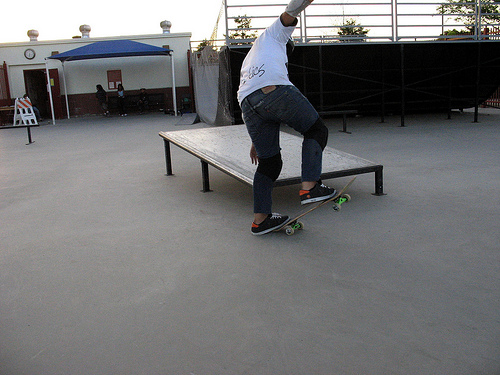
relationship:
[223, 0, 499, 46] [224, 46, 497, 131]
fence on top of wall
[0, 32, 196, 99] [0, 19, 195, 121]
wall of building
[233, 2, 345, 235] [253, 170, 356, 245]
man on skateboard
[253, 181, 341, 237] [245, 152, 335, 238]
sneakers on feet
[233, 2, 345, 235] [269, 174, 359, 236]
man on skateboard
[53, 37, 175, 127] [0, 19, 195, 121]
blue tent set up in front of building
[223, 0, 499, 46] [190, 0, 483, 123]
fence on bleachers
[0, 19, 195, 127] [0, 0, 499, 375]
building in park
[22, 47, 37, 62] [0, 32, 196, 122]
clock on wall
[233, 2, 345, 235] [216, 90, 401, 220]
man wearing jeans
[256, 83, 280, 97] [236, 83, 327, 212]
leather patch on blue jeans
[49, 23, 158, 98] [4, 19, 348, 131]
tent on front of building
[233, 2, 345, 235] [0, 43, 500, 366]
man in skate park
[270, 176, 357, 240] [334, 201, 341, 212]
skateboard has green wheel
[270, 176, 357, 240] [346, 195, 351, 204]
skateboard has green wheel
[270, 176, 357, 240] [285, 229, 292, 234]
skateboard has green wheel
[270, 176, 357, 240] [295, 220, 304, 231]
skateboard has green wheel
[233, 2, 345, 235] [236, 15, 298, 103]
man wearing shirt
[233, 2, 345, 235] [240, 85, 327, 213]
man wearing jeans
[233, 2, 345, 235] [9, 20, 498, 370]
man skateboarding in park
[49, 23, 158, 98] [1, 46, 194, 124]
tent on concrete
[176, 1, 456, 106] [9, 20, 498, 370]
fence around park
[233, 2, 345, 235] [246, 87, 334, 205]
man wearing jeans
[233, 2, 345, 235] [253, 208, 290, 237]
man wearing sneakers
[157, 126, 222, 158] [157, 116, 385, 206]
light reflection on ramp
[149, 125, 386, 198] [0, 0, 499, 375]
feature in park